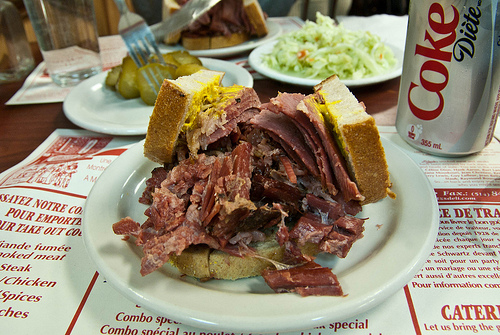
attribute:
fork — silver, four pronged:
[111, 0, 178, 96]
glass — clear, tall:
[22, 0, 103, 88]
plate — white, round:
[78, 128, 441, 334]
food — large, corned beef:
[123, 74, 385, 288]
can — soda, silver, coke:
[395, 0, 499, 156]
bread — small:
[143, 68, 225, 166]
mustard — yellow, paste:
[186, 75, 247, 126]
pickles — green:
[105, 48, 205, 106]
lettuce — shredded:
[267, 11, 395, 78]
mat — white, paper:
[1, 123, 499, 334]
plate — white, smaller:
[246, 34, 404, 87]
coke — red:
[407, 3, 458, 121]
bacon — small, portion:
[261, 267, 345, 296]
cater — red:
[440, 304, 500, 323]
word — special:
[328, 320, 371, 331]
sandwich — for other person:
[161, 0, 269, 51]